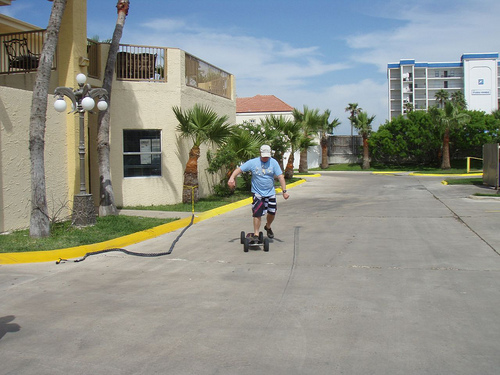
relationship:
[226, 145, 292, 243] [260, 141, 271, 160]
man wears cap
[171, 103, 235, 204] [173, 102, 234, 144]
tree has leaves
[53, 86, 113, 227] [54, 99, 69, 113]
pole has light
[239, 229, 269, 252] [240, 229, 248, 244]
skateboard has wheel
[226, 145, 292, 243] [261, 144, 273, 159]
man wears hat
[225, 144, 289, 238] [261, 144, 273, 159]
person wears hat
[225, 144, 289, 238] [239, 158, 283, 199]
person wears shirt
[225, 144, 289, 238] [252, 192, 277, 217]
person wears shorts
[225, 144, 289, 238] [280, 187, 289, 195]
person wears watch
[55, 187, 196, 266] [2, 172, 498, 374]
hose laying in street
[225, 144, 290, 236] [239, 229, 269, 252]
boy on skateboard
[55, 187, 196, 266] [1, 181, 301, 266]
hose by curb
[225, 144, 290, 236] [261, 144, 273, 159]
boy wears hat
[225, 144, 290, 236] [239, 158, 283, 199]
boy wears shirt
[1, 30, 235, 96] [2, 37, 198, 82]
balcony has furniture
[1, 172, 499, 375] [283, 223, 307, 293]
road has skid mark